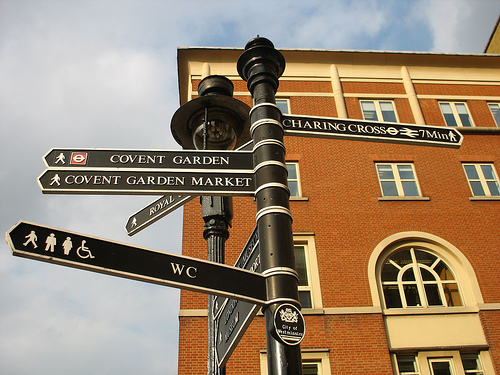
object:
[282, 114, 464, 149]
sign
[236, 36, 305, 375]
pole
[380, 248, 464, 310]
window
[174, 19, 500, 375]
building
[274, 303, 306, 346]
sign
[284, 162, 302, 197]
window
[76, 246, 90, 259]
wheelchair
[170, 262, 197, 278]
wc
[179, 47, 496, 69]
roof soffit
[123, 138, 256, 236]
sign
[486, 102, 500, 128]
windows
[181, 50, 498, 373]
front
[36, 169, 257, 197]
sign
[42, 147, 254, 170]
sign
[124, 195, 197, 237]
sign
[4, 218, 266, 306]
sign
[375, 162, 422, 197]
window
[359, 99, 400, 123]
window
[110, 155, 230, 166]
covent garden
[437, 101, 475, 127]
window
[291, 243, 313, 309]
window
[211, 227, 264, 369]
sign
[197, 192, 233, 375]
pole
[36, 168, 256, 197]
arrow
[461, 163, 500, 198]
window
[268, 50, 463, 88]
shingles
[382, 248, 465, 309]
mullions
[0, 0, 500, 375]
city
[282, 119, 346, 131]
charing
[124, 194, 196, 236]
partial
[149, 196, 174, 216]
royal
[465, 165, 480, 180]
glass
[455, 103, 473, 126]
glass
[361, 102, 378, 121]
glass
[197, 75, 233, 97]
top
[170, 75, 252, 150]
light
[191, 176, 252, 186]
market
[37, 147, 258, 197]
helpful